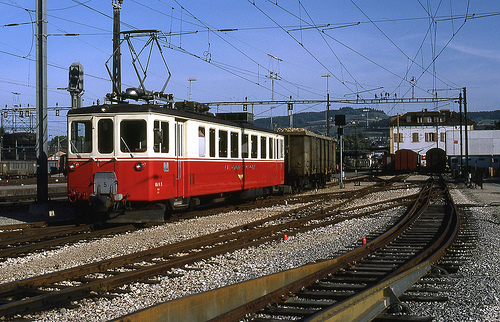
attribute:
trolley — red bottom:
[60, 97, 321, 226]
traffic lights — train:
[61, 58, 87, 98]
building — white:
[390, 113, 497, 173]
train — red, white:
[63, 103, 330, 232]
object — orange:
[354, 224, 375, 249]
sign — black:
[334, 113, 344, 135]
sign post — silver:
[337, 134, 345, 188]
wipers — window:
[117, 132, 134, 159]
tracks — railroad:
[403, 208, 459, 293]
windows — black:
[70, 112, 287, 160]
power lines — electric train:
[325, 30, 355, 54]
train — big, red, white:
[64, 100, 287, 223]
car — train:
[65, 103, 287, 226]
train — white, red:
[62, 92, 343, 222]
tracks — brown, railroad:
[33, 180, 350, 309]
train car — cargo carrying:
[276, 119, 344, 187]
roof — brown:
[388, 110, 473, 127]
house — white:
[390, 119, 499, 166]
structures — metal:
[7, 7, 469, 105]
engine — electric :
[61, 103, 287, 215]